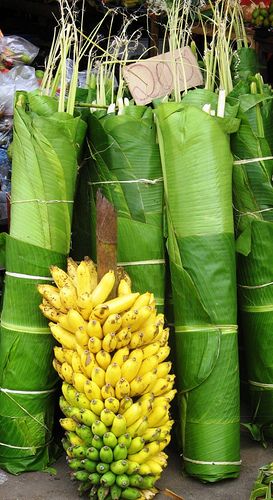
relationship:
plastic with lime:
[0, 30, 40, 69] [15, 42, 35, 64]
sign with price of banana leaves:
[116, 44, 208, 111] [6, 1, 268, 495]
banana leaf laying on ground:
[0, 48, 273, 499] [167, 480, 226, 498]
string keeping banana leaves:
[84, 176, 162, 188] [82, 103, 166, 317]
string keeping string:
[84, 176, 162, 188] [92, 257, 166, 267]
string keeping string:
[84, 176, 162, 188] [152, 297, 165, 306]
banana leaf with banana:
[0, 48, 273, 499] [36, 256, 177, 498]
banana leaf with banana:
[155, 88, 243, 488] [36, 256, 177, 498]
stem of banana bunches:
[90, 185, 118, 298] [39, 257, 175, 499]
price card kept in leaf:
[121, 46, 204, 105] [148, 93, 257, 420]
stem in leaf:
[246, 81, 256, 90] [230, 85, 269, 122]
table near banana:
[153, 9, 264, 82] [93, 289, 143, 318]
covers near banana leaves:
[0, 35, 39, 89] [15, 112, 222, 248]